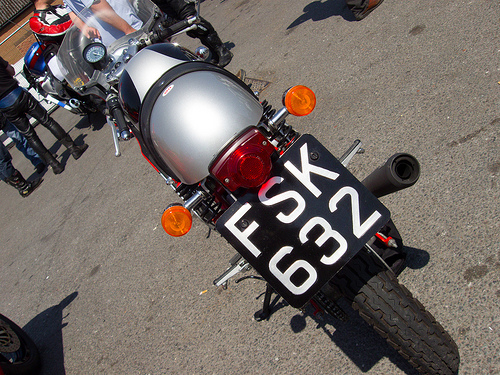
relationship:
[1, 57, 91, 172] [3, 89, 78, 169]
person wearing pants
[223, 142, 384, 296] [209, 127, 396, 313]
color on license plate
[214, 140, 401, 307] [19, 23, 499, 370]
license plate on motorcycle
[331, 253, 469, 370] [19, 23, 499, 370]
back tire on motorcycle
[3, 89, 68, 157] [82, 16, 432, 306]
pants on motorcycle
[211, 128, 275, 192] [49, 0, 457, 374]
light on motorcycle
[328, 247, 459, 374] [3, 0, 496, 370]
back tire on tarmack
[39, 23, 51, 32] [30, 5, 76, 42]
leather on jacket